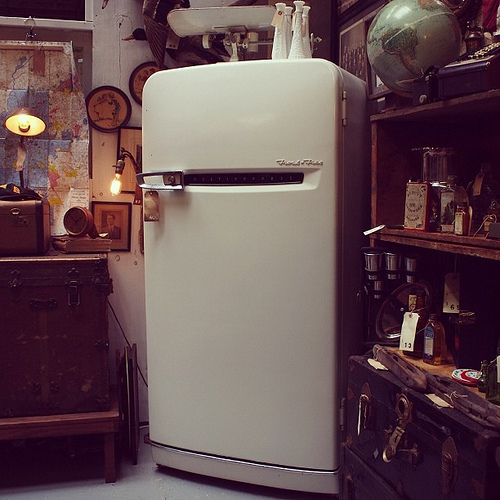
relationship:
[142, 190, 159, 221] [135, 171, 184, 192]
tag on handle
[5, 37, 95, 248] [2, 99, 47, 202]
map behind lamp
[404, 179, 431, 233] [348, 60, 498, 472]
antique on shelf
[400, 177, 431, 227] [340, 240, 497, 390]
antique on shelf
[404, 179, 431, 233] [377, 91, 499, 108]
antique on shelf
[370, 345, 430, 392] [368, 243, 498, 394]
antique on shelf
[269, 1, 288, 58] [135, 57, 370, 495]
vase on top of fridge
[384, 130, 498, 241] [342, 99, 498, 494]
items on shelf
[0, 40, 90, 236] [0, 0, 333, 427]
map hanging on wall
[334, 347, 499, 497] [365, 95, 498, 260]
chest under shelf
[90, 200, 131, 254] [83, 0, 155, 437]
frame on wall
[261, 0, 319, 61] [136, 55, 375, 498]
four vases on top of fridge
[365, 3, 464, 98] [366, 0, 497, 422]
globe on shelf